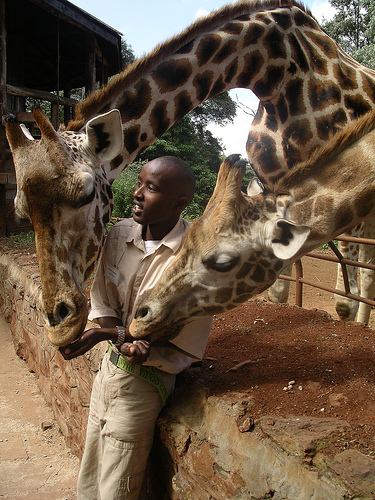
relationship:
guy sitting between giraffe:
[75, 154, 212, 499] [129, 133, 373, 344]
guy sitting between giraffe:
[75, 154, 212, 499] [1, 0, 374, 349]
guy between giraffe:
[75, 154, 212, 499] [1, 0, 374, 349]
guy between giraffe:
[75, 154, 212, 499] [130, 110, 374, 341]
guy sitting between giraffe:
[75, 154, 212, 499] [3, 2, 374, 396]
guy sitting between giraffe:
[75, 154, 212, 499] [33, 110, 123, 310]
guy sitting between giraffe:
[75, 154, 212, 499] [117, 115, 373, 353]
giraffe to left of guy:
[1, 0, 374, 349] [75, 154, 212, 499]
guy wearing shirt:
[75, 154, 212, 499] [75, 220, 217, 362]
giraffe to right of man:
[130, 110, 374, 341] [67, 152, 204, 495]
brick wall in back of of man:
[0, 244, 362, 497] [71, 151, 231, 442]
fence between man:
[270, 246, 355, 308] [105, 158, 219, 331]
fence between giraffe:
[270, 246, 355, 308] [140, 147, 355, 351]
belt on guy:
[92, 346, 171, 399] [75, 154, 212, 499]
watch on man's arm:
[113, 326, 125, 342] [94, 327, 145, 340]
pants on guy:
[76, 343, 176, 497] [75, 154, 212, 499]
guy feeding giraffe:
[59, 154, 212, 499] [130, 110, 374, 341]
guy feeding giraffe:
[59, 154, 212, 499] [1, 0, 374, 349]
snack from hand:
[58, 326, 75, 340] [57, 327, 104, 359]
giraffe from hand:
[130, 110, 374, 341] [121, 339, 150, 362]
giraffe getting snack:
[130, 110, 374, 341] [58, 326, 75, 340]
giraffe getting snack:
[1, 0, 374, 349] [58, 326, 75, 340]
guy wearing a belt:
[75, 154, 212, 499] [100, 337, 173, 402]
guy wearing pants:
[75, 154, 212, 499] [76, 343, 176, 497]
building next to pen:
[8, 1, 121, 88] [178, 149, 357, 307]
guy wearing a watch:
[75, 154, 212, 499] [110, 320, 129, 350]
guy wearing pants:
[75, 154, 212, 499] [76, 353, 164, 500]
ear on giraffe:
[263, 215, 314, 266] [130, 110, 374, 341]